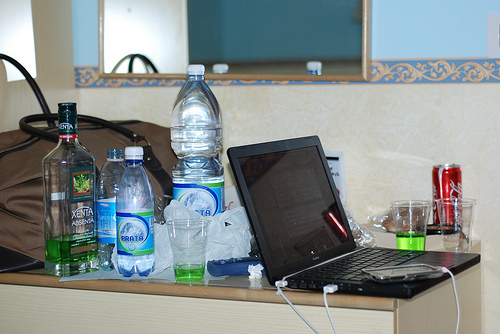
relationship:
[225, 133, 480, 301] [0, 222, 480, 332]
black laptop on table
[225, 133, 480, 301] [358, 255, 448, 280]
black laptop has device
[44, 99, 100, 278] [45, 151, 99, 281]
bottle has liquid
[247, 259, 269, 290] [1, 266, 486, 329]
paper on table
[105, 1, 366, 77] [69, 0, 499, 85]
mirror on wall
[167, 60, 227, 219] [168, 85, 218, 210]
bottle has water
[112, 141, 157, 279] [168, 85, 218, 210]
bottle has water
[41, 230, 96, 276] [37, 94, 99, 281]
bottle liquor in bottle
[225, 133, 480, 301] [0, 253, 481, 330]
black laptop on counter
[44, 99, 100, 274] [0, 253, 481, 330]
bottle on counter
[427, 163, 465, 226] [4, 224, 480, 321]
can on counter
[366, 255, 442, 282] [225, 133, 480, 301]
phone charging on black laptop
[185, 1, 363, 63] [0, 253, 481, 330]
mirror behind counter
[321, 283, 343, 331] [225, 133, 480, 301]
plug in black laptop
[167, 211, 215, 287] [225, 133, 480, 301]
cup near black laptop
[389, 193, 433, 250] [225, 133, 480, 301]
cup near black laptop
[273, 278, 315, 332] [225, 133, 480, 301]
cord connected to black laptop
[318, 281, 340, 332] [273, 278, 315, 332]
cord connected to cord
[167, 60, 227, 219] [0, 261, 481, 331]
bottle on counter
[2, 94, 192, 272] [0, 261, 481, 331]
bag on counter